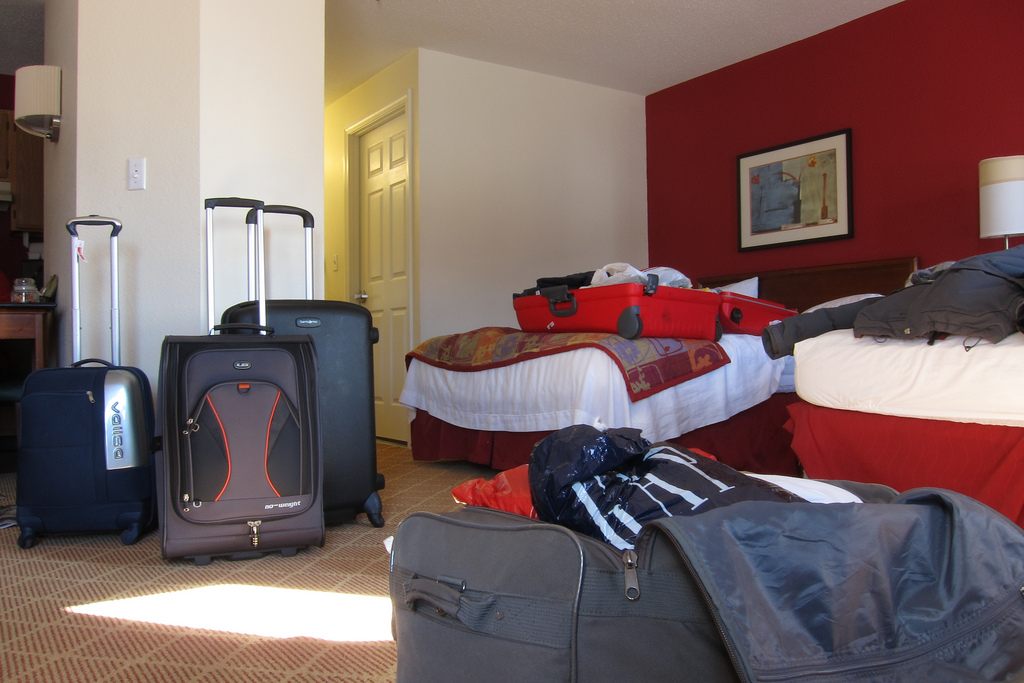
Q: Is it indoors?
A: Yes, it is indoors.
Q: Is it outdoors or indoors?
A: It is indoors.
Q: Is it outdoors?
A: No, it is indoors.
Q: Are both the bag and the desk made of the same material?
A: No, the bag is made of plastic and the desk is made of wood.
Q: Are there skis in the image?
A: No, there are no skis.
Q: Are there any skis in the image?
A: No, there are no skis.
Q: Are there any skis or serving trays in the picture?
A: No, there are no skis or serving trays.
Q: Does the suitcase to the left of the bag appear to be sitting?
A: No, the suitcase is standing.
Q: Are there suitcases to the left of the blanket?
A: Yes, there is a suitcase to the left of the blanket.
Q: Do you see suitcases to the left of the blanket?
A: Yes, there is a suitcase to the left of the blanket.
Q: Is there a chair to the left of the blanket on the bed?
A: No, there is a suitcase to the left of the blanket.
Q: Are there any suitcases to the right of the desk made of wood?
A: Yes, there is a suitcase to the right of the desk.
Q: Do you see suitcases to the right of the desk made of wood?
A: Yes, there is a suitcase to the right of the desk.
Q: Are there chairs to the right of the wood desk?
A: No, there is a suitcase to the right of the desk.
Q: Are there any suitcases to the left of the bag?
A: Yes, there is a suitcase to the left of the bag.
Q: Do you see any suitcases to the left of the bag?
A: Yes, there is a suitcase to the left of the bag.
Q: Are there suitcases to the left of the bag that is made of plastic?
A: Yes, there is a suitcase to the left of the bag.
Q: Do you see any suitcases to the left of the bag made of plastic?
A: Yes, there is a suitcase to the left of the bag.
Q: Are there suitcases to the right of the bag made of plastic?
A: No, the suitcase is to the left of the bag.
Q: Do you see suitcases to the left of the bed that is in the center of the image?
A: Yes, there is a suitcase to the left of the bed.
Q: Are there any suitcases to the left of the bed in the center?
A: Yes, there is a suitcase to the left of the bed.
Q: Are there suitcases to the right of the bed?
A: No, the suitcase is to the left of the bed.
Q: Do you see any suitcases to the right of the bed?
A: No, the suitcase is to the left of the bed.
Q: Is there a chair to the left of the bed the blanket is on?
A: No, there is a suitcase to the left of the bed.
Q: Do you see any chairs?
A: No, there are no chairs.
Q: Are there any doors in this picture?
A: Yes, there is a door.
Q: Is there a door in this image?
A: Yes, there is a door.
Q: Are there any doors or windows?
A: Yes, there is a door.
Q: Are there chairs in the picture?
A: No, there are no chairs.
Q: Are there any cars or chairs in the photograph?
A: No, there are no chairs or cars.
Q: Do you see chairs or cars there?
A: No, there are no chairs or cars.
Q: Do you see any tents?
A: No, there are no tents.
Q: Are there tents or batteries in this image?
A: No, there are no tents or batteries.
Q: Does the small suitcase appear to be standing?
A: Yes, the suitcase is standing.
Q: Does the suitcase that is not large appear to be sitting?
A: No, the suitcase is standing.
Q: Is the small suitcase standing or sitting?
A: The suitcase is standing.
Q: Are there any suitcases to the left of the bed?
A: Yes, there is a suitcase to the left of the bed.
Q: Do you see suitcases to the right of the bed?
A: No, the suitcase is to the left of the bed.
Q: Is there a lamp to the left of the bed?
A: No, there is a suitcase to the left of the bed.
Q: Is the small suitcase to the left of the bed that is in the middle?
A: Yes, the suitcase is to the left of the bed.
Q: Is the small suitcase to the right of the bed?
A: No, the suitcase is to the left of the bed.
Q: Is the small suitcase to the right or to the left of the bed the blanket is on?
A: The suitcase is to the left of the bed.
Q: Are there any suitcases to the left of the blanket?
A: Yes, there is a suitcase to the left of the blanket.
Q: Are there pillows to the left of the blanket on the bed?
A: No, there is a suitcase to the left of the blanket.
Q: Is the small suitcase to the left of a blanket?
A: Yes, the suitcase is to the left of a blanket.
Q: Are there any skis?
A: No, there are no skis.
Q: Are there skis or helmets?
A: No, there are no skis or helmets.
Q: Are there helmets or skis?
A: No, there are no skis or helmets.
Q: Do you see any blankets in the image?
A: Yes, there is a blanket.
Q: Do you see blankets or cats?
A: Yes, there is a blanket.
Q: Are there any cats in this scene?
A: No, there are no cats.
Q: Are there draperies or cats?
A: No, there are no cats or draperies.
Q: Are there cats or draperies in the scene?
A: No, there are no cats or draperies.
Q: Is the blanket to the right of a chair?
A: No, the blanket is to the right of the suitcase.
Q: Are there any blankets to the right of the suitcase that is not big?
A: Yes, there is a blanket to the right of the suitcase.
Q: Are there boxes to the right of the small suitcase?
A: No, there is a blanket to the right of the suitcase.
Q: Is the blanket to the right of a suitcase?
A: Yes, the blanket is to the right of a suitcase.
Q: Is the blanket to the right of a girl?
A: No, the blanket is to the right of a suitcase.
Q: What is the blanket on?
A: The blanket is on the bed.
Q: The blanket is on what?
A: The blanket is on the bed.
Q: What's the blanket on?
A: The blanket is on the bed.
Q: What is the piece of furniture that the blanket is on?
A: The piece of furniture is a bed.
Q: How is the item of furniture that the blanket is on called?
A: The piece of furniture is a bed.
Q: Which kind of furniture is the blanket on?
A: The blanket is on the bed.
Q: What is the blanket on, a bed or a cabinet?
A: The blanket is on a bed.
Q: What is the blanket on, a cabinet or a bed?
A: The blanket is on a bed.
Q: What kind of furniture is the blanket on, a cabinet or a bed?
A: The blanket is on a bed.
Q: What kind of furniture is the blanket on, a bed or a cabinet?
A: The blanket is on a bed.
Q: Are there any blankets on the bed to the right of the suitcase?
A: Yes, there is a blanket on the bed.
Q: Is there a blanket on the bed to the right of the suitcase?
A: Yes, there is a blanket on the bed.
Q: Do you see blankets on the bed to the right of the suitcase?
A: Yes, there is a blanket on the bed.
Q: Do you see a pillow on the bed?
A: No, there is a blanket on the bed.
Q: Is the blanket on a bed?
A: Yes, the blanket is on a bed.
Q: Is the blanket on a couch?
A: No, the blanket is on a bed.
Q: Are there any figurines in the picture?
A: No, there are no figurines.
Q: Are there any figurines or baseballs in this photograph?
A: No, there are no figurines or baseballs.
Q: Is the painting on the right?
A: Yes, the painting is on the right of the image.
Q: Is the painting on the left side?
A: No, the painting is on the right of the image.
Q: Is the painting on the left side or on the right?
A: The painting is on the right of the image.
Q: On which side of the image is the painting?
A: The painting is on the right of the image.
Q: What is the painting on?
A: The painting is on the wall.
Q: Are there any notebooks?
A: No, there are no notebooks.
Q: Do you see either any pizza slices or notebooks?
A: No, there are no notebooks or pizza slices.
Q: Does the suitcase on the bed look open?
A: Yes, the suitcase is open.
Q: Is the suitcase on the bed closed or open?
A: The suitcase is open.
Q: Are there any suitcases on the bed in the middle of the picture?
A: Yes, there is a suitcase on the bed.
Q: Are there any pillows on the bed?
A: No, there is a suitcase on the bed.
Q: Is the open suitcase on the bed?
A: Yes, the suitcase is on the bed.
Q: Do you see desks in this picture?
A: Yes, there is a desk.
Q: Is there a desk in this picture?
A: Yes, there is a desk.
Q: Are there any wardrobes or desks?
A: Yes, there is a desk.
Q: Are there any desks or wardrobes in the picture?
A: Yes, there is a desk.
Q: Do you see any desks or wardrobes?
A: Yes, there is a desk.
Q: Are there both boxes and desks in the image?
A: No, there is a desk but no boxes.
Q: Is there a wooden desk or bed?
A: Yes, there is a wood desk.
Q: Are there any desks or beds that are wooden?
A: Yes, the desk is wooden.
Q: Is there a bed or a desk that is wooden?
A: Yes, the desk is wooden.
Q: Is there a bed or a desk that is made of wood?
A: Yes, the desk is made of wood.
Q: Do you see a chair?
A: No, there are no chairs.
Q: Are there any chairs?
A: No, there are no chairs.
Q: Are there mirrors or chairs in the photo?
A: No, there are no chairs or mirrors.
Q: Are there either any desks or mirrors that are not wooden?
A: No, there is a desk but it is wooden.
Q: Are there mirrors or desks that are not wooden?
A: No, there is a desk but it is wooden.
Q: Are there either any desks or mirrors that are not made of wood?
A: No, there is a desk but it is made of wood.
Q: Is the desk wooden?
A: Yes, the desk is wooden.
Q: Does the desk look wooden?
A: Yes, the desk is wooden.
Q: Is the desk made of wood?
A: Yes, the desk is made of wood.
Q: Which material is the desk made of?
A: The desk is made of wood.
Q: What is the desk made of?
A: The desk is made of wood.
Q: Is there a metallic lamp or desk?
A: No, there is a desk but it is wooden.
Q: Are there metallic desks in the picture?
A: No, there is a desk but it is wooden.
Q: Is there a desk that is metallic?
A: No, there is a desk but it is wooden.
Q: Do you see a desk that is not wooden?
A: No, there is a desk but it is wooden.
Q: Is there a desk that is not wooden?
A: No, there is a desk but it is wooden.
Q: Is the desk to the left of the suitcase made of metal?
A: No, the desk is made of wood.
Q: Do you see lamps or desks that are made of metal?
A: No, there is a desk but it is made of wood.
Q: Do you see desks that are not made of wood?
A: No, there is a desk but it is made of wood.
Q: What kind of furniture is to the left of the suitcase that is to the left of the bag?
A: The piece of furniture is a desk.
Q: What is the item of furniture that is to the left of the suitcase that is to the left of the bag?
A: The piece of furniture is a desk.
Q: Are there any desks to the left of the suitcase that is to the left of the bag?
A: Yes, there is a desk to the left of the suitcase.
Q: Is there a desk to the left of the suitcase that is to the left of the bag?
A: Yes, there is a desk to the left of the suitcase.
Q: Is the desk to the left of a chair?
A: No, the desk is to the left of the suitcase.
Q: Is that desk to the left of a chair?
A: No, the desk is to the left of the suitcase.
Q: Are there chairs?
A: No, there are no chairs.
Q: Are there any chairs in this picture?
A: No, there are no chairs.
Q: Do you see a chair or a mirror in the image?
A: No, there are no chairs or mirrors.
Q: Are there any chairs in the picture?
A: No, there are no chairs.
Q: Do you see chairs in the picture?
A: No, there are no chairs.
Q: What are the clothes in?
A: The clothes are in the bag.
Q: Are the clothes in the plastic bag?
A: Yes, the clothes are in the bag.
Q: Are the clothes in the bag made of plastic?
A: Yes, the clothes are in the bag.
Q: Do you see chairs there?
A: No, there are no chairs.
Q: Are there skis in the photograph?
A: No, there are no skis.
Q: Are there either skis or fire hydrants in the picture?
A: No, there are no skis or fire hydrants.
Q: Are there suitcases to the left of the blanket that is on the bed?
A: Yes, there is a suitcase to the left of the blanket.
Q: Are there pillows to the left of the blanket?
A: No, there is a suitcase to the left of the blanket.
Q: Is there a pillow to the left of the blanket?
A: No, there is a suitcase to the left of the blanket.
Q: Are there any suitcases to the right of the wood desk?
A: Yes, there is a suitcase to the right of the desk.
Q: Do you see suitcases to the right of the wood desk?
A: Yes, there is a suitcase to the right of the desk.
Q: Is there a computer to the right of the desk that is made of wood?
A: No, there is a suitcase to the right of the desk.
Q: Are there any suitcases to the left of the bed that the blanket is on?
A: Yes, there is a suitcase to the left of the bed.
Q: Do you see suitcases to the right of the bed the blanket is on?
A: No, the suitcase is to the left of the bed.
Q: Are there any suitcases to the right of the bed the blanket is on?
A: No, the suitcase is to the left of the bed.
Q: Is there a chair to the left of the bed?
A: No, there is a suitcase to the left of the bed.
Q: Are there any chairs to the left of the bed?
A: No, there is a suitcase to the left of the bed.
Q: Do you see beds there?
A: Yes, there is a bed.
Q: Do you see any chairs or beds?
A: Yes, there is a bed.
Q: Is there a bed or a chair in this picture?
A: Yes, there is a bed.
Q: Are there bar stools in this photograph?
A: No, there are no bar stools.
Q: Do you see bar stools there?
A: No, there are no bar stools.